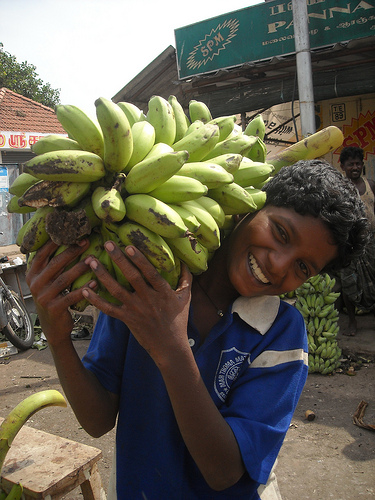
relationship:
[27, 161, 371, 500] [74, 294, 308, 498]
boy in shirt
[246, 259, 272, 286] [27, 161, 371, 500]
teeth of boy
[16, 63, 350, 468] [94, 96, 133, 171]
boy carrying banana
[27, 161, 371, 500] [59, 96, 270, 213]
boy carrying bananas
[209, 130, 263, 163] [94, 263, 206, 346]
banana on shoulder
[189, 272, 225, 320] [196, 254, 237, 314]
necklace on neck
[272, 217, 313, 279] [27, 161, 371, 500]
eyes of boy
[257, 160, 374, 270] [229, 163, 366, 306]
curly hair on head